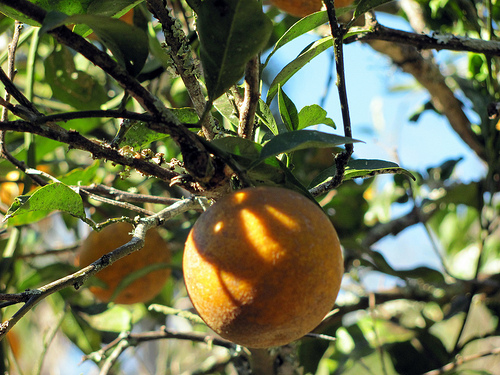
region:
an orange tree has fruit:
[7, 3, 494, 368]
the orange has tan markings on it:
[182, 185, 342, 351]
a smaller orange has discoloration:
[79, 219, 171, 306]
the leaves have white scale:
[192, 1, 262, 93]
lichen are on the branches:
[145, 2, 208, 87]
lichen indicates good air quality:
[136, 1, 226, 129]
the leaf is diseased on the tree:
[115, 105, 196, 152]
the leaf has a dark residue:
[301, 164, 416, 199]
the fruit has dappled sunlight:
[8, 7, 486, 364]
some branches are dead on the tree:
[151, 1, 224, 152]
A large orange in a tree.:
[174, 172, 354, 360]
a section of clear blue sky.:
[250, 25, 492, 191]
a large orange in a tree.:
[171, 180, 369, 356]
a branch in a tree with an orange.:
[9, 98, 216, 200]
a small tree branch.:
[321, 0, 356, 170]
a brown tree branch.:
[9, 177, 214, 326]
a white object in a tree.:
[370, 89, 395, 156]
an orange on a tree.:
[75, 206, 190, 322]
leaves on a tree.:
[421, 196, 498, 282]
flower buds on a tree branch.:
[127, 137, 204, 201]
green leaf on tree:
[252, 127, 364, 163]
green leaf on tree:
[321, 157, 415, 197]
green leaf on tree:
[275, 83, 300, 132]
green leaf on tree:
[295, 102, 336, 131]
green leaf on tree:
[6, 184, 85, 226]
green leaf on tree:
[117, 105, 196, 150]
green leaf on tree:
[55, 162, 100, 189]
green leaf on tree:
[3, 262, 104, 297]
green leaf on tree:
[316, 314, 417, 374]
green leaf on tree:
[42, 297, 105, 368]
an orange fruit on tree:
[182, 188, 343, 348]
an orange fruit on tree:
[75, 225, 168, 303]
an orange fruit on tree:
[4, 165, 51, 226]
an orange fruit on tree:
[0, 325, 21, 371]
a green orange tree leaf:
[197, 0, 275, 105]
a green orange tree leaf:
[260, 5, 353, 71]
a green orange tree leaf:
[265, 28, 366, 108]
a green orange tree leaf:
[307, 157, 416, 192]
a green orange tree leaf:
[275, 81, 300, 130]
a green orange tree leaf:
[295, 102, 335, 129]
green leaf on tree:
[341, 154, 419, 180]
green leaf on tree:
[190, 2, 270, 97]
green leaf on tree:
[42, 14, 152, 75]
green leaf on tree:
[262, 6, 347, 71]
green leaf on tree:
[259, 26, 371, 106]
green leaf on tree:
[10, 106, 105, 169]